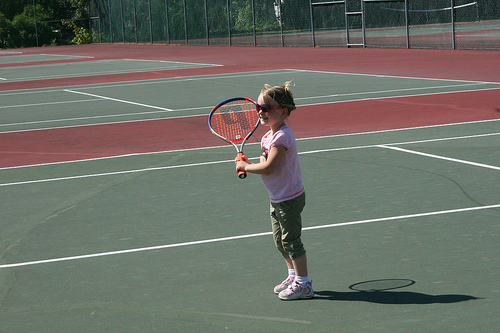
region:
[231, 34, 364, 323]
a kid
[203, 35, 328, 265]
a kid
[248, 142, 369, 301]
a kid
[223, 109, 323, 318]
a kid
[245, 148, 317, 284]
a kid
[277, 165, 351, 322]
a kid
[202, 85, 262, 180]
The tennis racket held by the girl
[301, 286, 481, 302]
The girl's shadow on the ground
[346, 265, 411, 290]
The shadow of the racket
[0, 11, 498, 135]
The unused courts to the girl's right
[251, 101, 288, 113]
The girl's sunglasses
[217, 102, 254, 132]
The 'P' on the tennis racket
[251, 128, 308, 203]
The girl's pink shirt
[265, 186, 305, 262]
The girl's green pants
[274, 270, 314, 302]
The whit and pink shoes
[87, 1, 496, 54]
The fence separating the courts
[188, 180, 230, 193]
part of a court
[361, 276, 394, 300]
part of a shade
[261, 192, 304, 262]
part of a short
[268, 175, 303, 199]
edge of a top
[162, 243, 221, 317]
part of a court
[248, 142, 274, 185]
part of an elbow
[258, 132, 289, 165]
part of a bicep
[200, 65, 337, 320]
The girl is holding a tennis racket.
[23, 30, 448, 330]
The girl is standing on a tennis court.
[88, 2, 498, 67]
The fence is metal.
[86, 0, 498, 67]
The fence is tall.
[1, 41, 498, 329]
White lines on the tennis court.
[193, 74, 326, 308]
The girl is smiling.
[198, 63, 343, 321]
The girl is wearing sunglasses.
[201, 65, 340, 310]
The girl's hair is up off her neck.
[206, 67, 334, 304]
The girl is wearing a pink shirt.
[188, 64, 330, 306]
The girl is wearing tennis shoes.